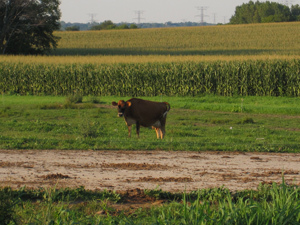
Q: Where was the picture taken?
A: A field.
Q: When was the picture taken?
A: Daytime.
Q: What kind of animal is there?
A: A cow.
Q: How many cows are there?
A: One.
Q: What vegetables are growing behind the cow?
A: Corn.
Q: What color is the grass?
A: Green.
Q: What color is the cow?
A: Brown.